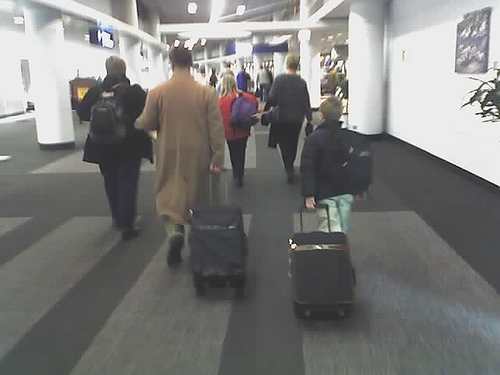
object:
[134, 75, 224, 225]
coat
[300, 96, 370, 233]
people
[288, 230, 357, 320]
suitcases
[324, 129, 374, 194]
backpack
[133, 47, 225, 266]
man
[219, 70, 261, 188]
woman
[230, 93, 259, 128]
backpack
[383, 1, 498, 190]
wall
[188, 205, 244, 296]
suitcase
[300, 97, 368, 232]
boy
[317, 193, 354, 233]
pants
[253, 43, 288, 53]
banner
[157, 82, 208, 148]
backs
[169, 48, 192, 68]
head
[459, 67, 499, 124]
leaves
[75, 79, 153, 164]
coat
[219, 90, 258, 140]
coat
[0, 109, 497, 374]
floor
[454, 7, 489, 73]
picture